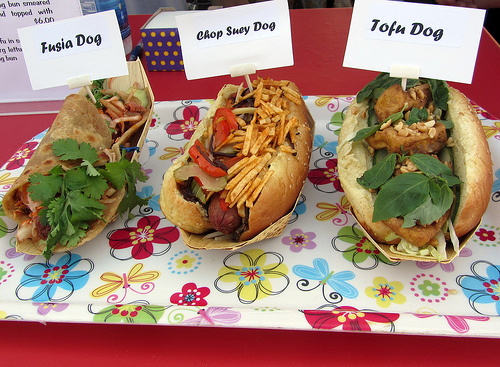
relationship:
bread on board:
[158, 75, 314, 242] [0, 95, 500, 339]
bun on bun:
[336, 83, 494, 247] [345, 73, 484, 255]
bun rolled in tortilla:
[1, 89, 150, 252] [6, 92, 116, 225]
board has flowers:
[0, 95, 500, 339] [24, 239, 441, 334]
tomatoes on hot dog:
[195, 113, 230, 173] [170, 74, 302, 232]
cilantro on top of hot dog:
[25, 136, 147, 260] [2, 58, 154, 253]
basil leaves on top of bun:
[355, 150, 464, 229] [336, 83, 494, 247]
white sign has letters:
[343, 0, 488, 87] [371, 11, 443, 41]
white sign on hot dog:
[343, 0, 488, 87] [339, 83, 477, 252]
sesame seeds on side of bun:
[460, 89, 497, 205] [337, 75, 484, 243]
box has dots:
[138, 3, 226, 73] [140, 30, 187, 73]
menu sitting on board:
[1, 3, 101, 108] [0, 95, 500, 339]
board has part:
[0, 96, 494, 325] [386, 253, 400, 263]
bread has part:
[156, 66, 323, 246] [244, 210, 254, 217]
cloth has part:
[306, 214, 366, 325] [242, 287, 264, 314]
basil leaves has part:
[356, 144, 465, 228] [407, 161, 421, 186]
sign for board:
[162, 3, 312, 94] [0, 95, 500, 339]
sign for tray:
[12, 12, 132, 83] [15, 112, 498, 345]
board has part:
[0, 95, 500, 339] [147, 245, 250, 299]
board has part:
[0, 95, 500, 339] [303, 259, 408, 299]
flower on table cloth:
[233, 274, 265, 289] [15, 260, 482, 323]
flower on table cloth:
[108, 213, 179, 261] [2, 75, 499, 338]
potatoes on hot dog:
[219, 75, 304, 218] [156, 75, 314, 243]